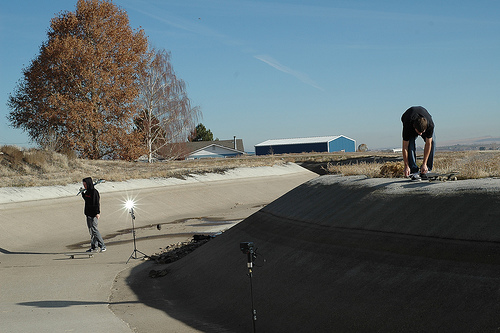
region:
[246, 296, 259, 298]
part of a camera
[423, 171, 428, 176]
part of a board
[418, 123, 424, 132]
head of a man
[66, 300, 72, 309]
part of a shadow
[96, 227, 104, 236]
part of a trouser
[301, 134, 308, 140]
part of a roof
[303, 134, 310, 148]
part of a building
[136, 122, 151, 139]
part of a branch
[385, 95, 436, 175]
male skateboarder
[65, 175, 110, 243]
male skateboarder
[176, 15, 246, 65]
white clouds in blue sky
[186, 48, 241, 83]
white clouds in blue sky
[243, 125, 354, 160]
long building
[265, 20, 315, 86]
white clouds in blue sky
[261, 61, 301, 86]
white clouds in blue sky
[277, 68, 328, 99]
white clouds in blue sky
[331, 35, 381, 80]
white clouds in blue sky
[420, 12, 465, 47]
white clouds in blue sky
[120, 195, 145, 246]
a camera reflecting light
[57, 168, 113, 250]
a person hold a metal rod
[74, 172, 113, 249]
a person wearing a black hoodie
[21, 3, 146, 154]
brown leaves covering a tree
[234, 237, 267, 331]
a camera on a tripod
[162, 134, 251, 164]
a blue house behind a hill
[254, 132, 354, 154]
a small blue building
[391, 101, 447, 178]
a person tying a shoe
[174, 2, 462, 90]
a clear blue autumn sky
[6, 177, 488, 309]
a cement skate park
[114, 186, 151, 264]
light on a tripod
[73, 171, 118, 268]
person on the asphalt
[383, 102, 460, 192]
man bending down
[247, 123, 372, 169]
blue barn in the background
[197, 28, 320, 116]
line of white wispy clouds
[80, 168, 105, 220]
black hoody on a man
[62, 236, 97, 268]
skateboard on the ground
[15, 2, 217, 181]
group of trees in the background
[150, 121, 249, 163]
roof of a house in the distance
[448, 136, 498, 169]
hilly land in the distance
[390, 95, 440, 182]
A man fixing his shoe.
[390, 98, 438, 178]
A man wearing a black shirt.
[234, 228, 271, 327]
A light on a stand.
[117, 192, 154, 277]
A light on a stand.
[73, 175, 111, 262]
A man wearing a black sweater.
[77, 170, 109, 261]
A man wearing grey pants.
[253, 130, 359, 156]
A blue barn with a white roof.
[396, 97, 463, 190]
A man standing next to a skateboard.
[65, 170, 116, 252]
A man carrying a skateboard.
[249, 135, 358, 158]
The blue barn has a white roof.